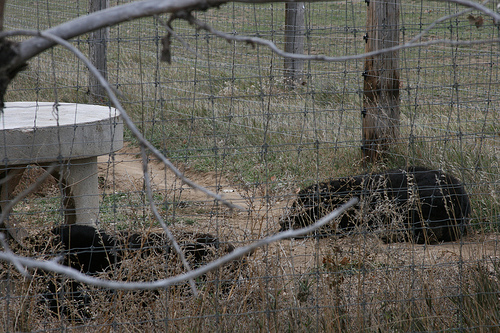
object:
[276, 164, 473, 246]
bear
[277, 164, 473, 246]
dog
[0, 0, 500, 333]
fence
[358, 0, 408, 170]
post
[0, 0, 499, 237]
grass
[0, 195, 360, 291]
tree limb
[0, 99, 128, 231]
structure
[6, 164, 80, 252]
space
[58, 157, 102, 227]
leg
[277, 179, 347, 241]
head